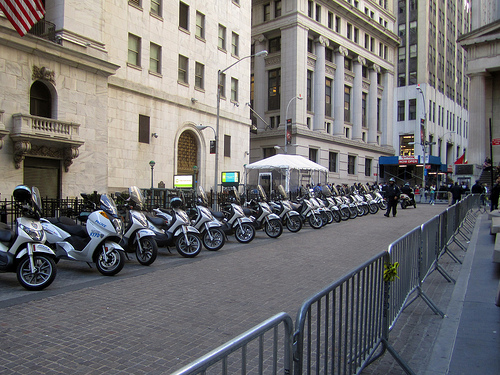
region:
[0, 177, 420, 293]
A row of motorbikes.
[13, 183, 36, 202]
A helmet on the handlebars of a motorbike.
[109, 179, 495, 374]
Silver rail fence.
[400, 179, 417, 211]
A person an a motorbike.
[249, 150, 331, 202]
A white event tent.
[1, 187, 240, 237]
A black metal fence behind the motorbikes.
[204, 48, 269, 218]
A street light.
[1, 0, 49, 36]
Part of an American flag.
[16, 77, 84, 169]
A balcony on a light brick building.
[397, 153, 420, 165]
A red and white sign on a building.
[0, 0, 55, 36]
Part of an American flag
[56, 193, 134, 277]
A police motorcycle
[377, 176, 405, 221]
A police man with a helmet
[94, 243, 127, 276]
Front tire on a police motorcycle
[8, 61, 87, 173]
A Balcony on a building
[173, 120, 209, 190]
Doors to a building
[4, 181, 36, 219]
A helmet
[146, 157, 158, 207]
A lamp post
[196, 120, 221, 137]
A street light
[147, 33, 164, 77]
A window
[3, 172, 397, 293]
a row of mopeds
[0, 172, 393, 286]
the mopeds are black and silver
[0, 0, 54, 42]
a portion of a flag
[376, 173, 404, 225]
a man walking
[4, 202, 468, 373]
the walkway is brick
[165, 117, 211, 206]
an entrance to the building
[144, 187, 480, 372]
a metal barricade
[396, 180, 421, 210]
a person riding on a moped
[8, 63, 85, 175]
a small balcony on the building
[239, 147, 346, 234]
a white tent behind the mopeds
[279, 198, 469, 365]
metal fence barriers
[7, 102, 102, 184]
a stone balcony on a building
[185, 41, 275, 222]
a metal light pole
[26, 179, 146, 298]
a white motorcycle parked on the street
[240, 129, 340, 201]
white tent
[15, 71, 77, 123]
window of a building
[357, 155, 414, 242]
person wearing black walking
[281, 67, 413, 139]
a building with pillars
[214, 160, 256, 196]
a billboard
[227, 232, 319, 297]
bricks on the ground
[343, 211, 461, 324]
metal temporary barrier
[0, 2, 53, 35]
part of an American flag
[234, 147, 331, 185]
white canopy tent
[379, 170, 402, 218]
person walking down the walk way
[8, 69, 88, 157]
window with balcony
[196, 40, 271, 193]
light post on the sidewalk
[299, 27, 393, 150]
windows in a building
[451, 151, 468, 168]
red flag in the distance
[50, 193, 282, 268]
row of motorcycles parked in a line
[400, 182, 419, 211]
Person riding a motorcycle